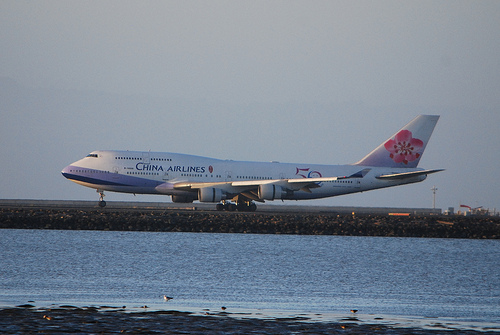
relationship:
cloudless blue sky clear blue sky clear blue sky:
[105, 16, 286, 131] [163, 25, 288, 114]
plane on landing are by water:
[47, 105, 455, 269] [131, 240, 450, 315]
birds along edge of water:
[28, 277, 393, 333] [102, 254, 386, 323]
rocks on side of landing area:
[10, 208, 111, 231] [8, 198, 181, 232]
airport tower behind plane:
[415, 166, 454, 240] [48, 113, 448, 223]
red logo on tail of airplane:
[363, 117, 453, 185] [61, 111, 441, 212]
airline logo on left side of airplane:
[118, 151, 228, 189] [61, 111, 441, 212]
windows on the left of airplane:
[60, 139, 131, 199] [61, 111, 441, 212]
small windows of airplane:
[101, 147, 191, 170] [61, 111, 441, 212]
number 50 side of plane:
[276, 153, 338, 213] [63, 112, 441, 216]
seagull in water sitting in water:
[149, 273, 187, 318] [5, 228, 493, 303]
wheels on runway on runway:
[81, 176, 275, 237] [3, 206, 497, 231]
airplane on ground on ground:
[47, 105, 455, 269] [0, 209, 499, 232]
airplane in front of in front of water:
[61, 111, 441, 212] [47, 105, 455, 269]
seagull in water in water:
[158, 288, 181, 305] [5, 236, 492, 304]